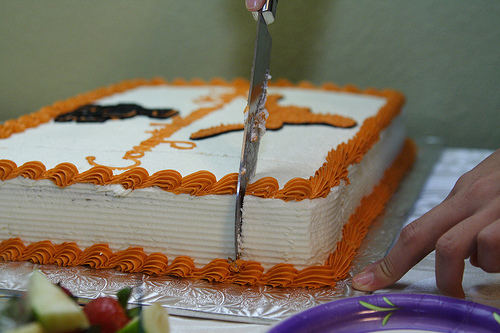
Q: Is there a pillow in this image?
A: No, there are no pillows.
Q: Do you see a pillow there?
A: No, there are no pillows.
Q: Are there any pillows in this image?
A: No, there are no pillows.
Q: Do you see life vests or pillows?
A: No, there are no pillows or life vests.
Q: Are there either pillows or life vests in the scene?
A: No, there are no pillows or life vests.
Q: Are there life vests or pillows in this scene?
A: No, there are no pillows or life vests.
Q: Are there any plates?
A: Yes, there is a plate.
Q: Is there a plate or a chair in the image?
A: Yes, there is a plate.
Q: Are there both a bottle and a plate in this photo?
A: No, there is a plate but no bottles.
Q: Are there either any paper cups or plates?
A: Yes, there is a paper plate.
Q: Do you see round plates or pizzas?
A: Yes, there is a round plate.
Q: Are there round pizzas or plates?
A: Yes, there is a round plate.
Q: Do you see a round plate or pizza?
A: Yes, there is a round plate.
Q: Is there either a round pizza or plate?
A: Yes, there is a round plate.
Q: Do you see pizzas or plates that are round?
A: Yes, the plate is round.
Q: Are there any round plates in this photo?
A: Yes, there is a round plate.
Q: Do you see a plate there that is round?
A: Yes, there is a round plate.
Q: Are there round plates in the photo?
A: Yes, there is a round plate.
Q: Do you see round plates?
A: Yes, there is a round plate.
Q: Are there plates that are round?
A: Yes, there is a plate that is round.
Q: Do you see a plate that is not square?
A: Yes, there is a round plate.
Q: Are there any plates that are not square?
A: Yes, there is a round plate.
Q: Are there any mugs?
A: No, there are no mugs.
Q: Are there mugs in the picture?
A: No, there are no mugs.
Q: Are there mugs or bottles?
A: No, there are no mugs or bottles.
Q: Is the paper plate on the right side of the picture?
A: Yes, the plate is on the right of the image.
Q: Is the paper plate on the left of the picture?
A: No, the plate is on the right of the image.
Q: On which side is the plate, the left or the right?
A: The plate is on the right of the image.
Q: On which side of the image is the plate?
A: The plate is on the right of the image.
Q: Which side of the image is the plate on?
A: The plate is on the right of the image.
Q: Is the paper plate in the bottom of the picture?
A: Yes, the plate is in the bottom of the image.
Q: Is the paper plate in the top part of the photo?
A: No, the plate is in the bottom of the image.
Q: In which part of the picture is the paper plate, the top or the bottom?
A: The plate is in the bottom of the image.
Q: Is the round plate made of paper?
A: Yes, the plate is made of paper.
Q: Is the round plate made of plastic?
A: No, the plate is made of paper.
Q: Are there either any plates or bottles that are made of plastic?
A: No, there is a plate but it is made of paper.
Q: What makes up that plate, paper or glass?
A: The plate is made of paper.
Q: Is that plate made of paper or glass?
A: The plate is made of paper.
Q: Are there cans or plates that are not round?
A: No, there is a plate but it is round.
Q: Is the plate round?
A: Yes, the plate is round.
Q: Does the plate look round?
A: Yes, the plate is round.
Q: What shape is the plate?
A: The plate is round.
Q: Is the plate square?
A: No, the plate is round.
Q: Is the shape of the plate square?
A: No, the plate is round.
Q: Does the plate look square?
A: No, the plate is round.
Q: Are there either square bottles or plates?
A: No, there is a plate but it is round.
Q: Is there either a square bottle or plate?
A: No, there is a plate but it is round.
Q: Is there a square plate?
A: No, there is a plate but it is round.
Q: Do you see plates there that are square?
A: No, there is a plate but it is round.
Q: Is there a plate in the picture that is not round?
A: No, there is a plate but it is round.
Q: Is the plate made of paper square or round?
A: The plate is round.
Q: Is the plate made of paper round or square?
A: The plate is round.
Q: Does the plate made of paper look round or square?
A: The plate is round.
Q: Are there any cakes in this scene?
A: Yes, there is a cake.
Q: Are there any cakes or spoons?
A: Yes, there is a cake.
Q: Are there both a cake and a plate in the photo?
A: Yes, there are both a cake and a plate.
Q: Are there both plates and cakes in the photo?
A: Yes, there are both a cake and a plate.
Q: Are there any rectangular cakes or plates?
A: Yes, there is a rectangular cake.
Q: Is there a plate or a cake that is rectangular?
A: Yes, the cake is rectangular.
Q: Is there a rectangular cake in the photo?
A: Yes, there is a rectangular cake.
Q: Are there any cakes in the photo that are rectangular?
A: Yes, there is a cake that is rectangular.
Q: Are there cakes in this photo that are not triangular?
A: Yes, there is a rectangular cake.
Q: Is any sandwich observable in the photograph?
A: No, there are no sandwiches.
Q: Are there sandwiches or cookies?
A: No, there are no sandwiches or cookies.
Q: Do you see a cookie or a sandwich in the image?
A: No, there are no sandwiches or cookies.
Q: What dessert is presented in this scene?
A: The dessert is a cake.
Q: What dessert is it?
A: The dessert is a cake.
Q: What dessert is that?
A: This is a cake.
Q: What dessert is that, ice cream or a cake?
A: This is a cake.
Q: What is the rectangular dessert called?
A: The dessert is a cake.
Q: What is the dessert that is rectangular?
A: The dessert is a cake.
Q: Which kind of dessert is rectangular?
A: The dessert is a cake.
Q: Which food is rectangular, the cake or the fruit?
A: The cake is rectangular.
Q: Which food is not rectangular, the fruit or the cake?
A: The fruit is not rectangular.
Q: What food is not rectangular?
A: The food is a fruit.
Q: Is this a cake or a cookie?
A: This is a cake.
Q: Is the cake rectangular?
A: Yes, the cake is rectangular.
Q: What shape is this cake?
A: The cake is rectangular.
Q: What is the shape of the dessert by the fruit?
A: The cake is rectangular.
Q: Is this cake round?
A: No, the cake is rectangular.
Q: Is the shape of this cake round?
A: No, the cake is rectangular.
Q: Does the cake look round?
A: No, the cake is rectangular.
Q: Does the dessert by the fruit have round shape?
A: No, the cake is rectangular.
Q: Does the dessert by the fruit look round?
A: No, the cake is rectangular.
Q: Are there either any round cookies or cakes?
A: No, there is a cake but it is rectangular.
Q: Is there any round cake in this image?
A: No, there is a cake but it is rectangular.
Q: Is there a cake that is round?
A: No, there is a cake but it is rectangular.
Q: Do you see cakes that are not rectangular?
A: No, there is a cake but it is rectangular.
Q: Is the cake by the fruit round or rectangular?
A: The cake is rectangular.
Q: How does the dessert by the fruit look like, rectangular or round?
A: The cake is rectangular.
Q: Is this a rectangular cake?
A: Yes, this is a rectangular cake.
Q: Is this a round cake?
A: No, this is a rectangular cake.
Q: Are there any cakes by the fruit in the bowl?
A: Yes, there is a cake by the fruit.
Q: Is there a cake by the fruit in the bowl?
A: Yes, there is a cake by the fruit.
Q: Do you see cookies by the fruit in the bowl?
A: No, there is a cake by the fruit.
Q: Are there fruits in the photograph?
A: Yes, there is a fruit.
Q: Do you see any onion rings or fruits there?
A: Yes, there is a fruit.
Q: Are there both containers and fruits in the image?
A: No, there is a fruit but no containers.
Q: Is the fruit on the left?
A: Yes, the fruit is on the left of the image.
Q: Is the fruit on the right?
A: No, the fruit is on the left of the image.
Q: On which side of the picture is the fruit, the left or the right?
A: The fruit is on the left of the image.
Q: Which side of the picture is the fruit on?
A: The fruit is on the left of the image.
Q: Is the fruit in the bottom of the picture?
A: Yes, the fruit is in the bottom of the image.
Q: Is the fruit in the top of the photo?
A: No, the fruit is in the bottom of the image.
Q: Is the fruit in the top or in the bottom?
A: The fruit is in the bottom of the image.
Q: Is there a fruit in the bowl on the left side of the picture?
A: Yes, there is a fruit in the bowl.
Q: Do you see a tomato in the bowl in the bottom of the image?
A: No, there is a fruit in the bowl.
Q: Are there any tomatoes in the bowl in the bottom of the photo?
A: No, there is a fruit in the bowl.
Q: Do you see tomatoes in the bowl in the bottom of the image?
A: No, there is a fruit in the bowl.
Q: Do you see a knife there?
A: Yes, there is a knife.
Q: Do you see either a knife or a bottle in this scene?
A: Yes, there is a knife.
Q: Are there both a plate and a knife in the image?
A: Yes, there are both a knife and a plate.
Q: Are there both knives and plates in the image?
A: Yes, there are both a knife and a plate.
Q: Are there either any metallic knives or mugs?
A: Yes, there is a metal knife.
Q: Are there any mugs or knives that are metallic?
A: Yes, the knife is metallic.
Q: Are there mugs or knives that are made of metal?
A: Yes, the knife is made of metal.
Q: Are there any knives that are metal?
A: Yes, there is a metal knife.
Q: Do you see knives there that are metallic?
A: Yes, there is a knife that is metallic.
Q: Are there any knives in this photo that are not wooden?
A: Yes, there is a metallic knife.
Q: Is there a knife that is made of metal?
A: Yes, there is a knife that is made of metal.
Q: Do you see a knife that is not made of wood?
A: Yes, there is a knife that is made of metal.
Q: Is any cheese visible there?
A: No, there is no cheese.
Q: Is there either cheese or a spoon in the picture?
A: No, there are no cheese or spoons.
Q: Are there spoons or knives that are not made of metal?
A: No, there is a knife but it is made of metal.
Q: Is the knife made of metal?
A: Yes, the knife is made of metal.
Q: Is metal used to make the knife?
A: Yes, the knife is made of metal.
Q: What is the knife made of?
A: The knife is made of metal.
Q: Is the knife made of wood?
A: No, the knife is made of metal.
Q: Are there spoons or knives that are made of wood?
A: No, there is a knife but it is made of metal.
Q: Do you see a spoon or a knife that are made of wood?
A: No, there is a knife but it is made of metal.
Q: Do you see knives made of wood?
A: No, there is a knife but it is made of metal.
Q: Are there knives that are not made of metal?
A: No, there is a knife but it is made of metal.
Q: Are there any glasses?
A: No, there are no glasses.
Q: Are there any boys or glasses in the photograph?
A: No, there are no glasses or boys.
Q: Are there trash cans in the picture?
A: No, there are no trash cans.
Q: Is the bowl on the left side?
A: Yes, the bowl is on the left of the image.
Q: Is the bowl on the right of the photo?
A: No, the bowl is on the left of the image.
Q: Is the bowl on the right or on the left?
A: The bowl is on the left of the image.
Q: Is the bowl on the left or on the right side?
A: The bowl is on the left of the image.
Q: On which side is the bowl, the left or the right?
A: The bowl is on the left of the image.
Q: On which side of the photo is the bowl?
A: The bowl is on the left of the image.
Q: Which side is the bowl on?
A: The bowl is on the left of the image.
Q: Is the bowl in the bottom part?
A: Yes, the bowl is in the bottom of the image.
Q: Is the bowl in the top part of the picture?
A: No, the bowl is in the bottom of the image.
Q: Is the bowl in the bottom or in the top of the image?
A: The bowl is in the bottom of the image.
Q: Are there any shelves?
A: No, there are no shelves.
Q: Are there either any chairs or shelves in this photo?
A: No, there are no shelves or chairs.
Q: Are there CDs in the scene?
A: No, there are no cds.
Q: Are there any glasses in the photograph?
A: No, there are no glasses.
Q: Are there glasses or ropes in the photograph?
A: No, there are no glasses or ropes.